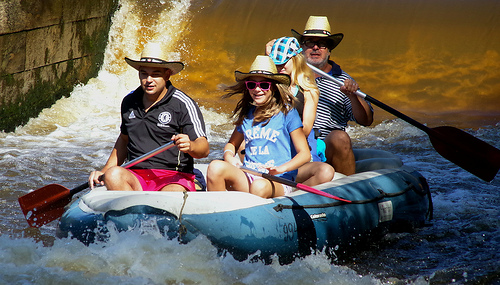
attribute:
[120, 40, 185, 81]
hat — tan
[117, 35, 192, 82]
hat — cowboy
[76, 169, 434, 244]
raft — blue, white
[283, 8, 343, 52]
hat — cowboy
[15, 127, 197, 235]
paddle — red, blue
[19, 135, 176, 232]
paddle — large, red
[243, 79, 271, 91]
sunglasses — pink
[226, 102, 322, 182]
shirt — blue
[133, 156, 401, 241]
boat — raft, light blue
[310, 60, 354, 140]
shirt — striped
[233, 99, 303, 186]
shirt — blue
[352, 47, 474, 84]
water — brown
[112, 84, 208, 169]
shirt — black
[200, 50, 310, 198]
girl — smiling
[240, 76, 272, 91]
glasses — pink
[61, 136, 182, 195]
handle — pink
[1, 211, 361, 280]
water — white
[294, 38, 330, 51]
glasses — black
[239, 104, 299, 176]
t shirt — blue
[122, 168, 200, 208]
shorts — red